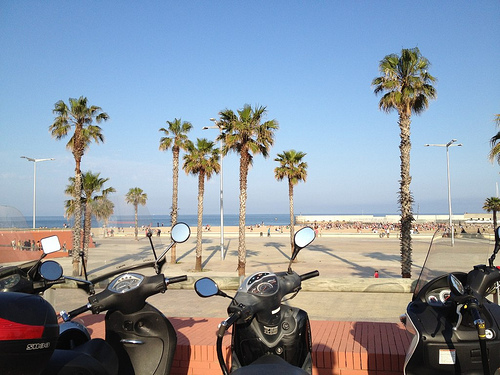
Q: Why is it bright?
A: It's sunny.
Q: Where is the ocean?
A: In the background.